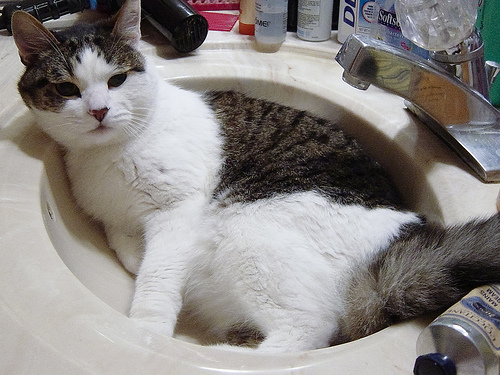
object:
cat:
[8, 0, 500, 353]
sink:
[37, 77, 448, 350]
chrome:
[369, 58, 382, 69]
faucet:
[332, 32, 499, 180]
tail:
[349, 211, 500, 340]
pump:
[373, 7, 398, 32]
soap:
[373, 1, 436, 65]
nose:
[90, 107, 109, 121]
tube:
[254, 0, 287, 43]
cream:
[239, 0, 258, 36]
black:
[253, 16, 267, 25]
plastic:
[424, 17, 438, 31]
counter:
[140, 9, 335, 43]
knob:
[393, 0, 489, 65]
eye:
[106, 70, 127, 90]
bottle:
[253, 0, 287, 43]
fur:
[78, 41, 98, 58]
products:
[251, 0, 290, 44]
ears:
[105, 0, 148, 41]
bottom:
[254, 29, 286, 44]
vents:
[190, 25, 196, 28]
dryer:
[141, 1, 212, 54]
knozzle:
[172, 13, 210, 56]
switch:
[81, 0, 109, 13]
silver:
[268, 12, 276, 28]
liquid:
[255, 12, 285, 44]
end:
[170, 16, 209, 52]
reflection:
[356, 51, 373, 64]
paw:
[130, 300, 176, 339]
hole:
[42, 204, 55, 222]